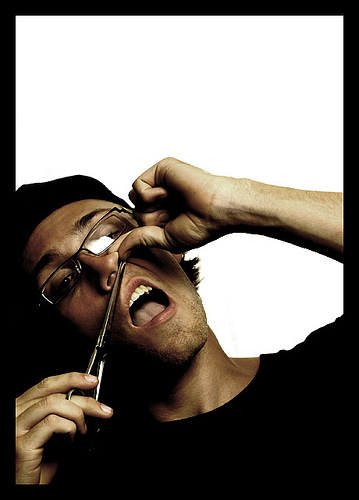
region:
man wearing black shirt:
[267, 401, 341, 461]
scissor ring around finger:
[61, 388, 78, 400]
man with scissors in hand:
[62, 352, 118, 432]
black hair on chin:
[171, 330, 200, 354]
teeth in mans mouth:
[134, 286, 146, 295]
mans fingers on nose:
[110, 240, 131, 257]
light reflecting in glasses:
[87, 238, 112, 249]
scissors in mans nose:
[115, 257, 126, 267]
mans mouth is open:
[119, 278, 179, 327]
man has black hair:
[187, 257, 198, 279]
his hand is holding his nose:
[108, 157, 225, 263]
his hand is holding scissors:
[13, 260, 123, 480]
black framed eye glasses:
[37, 212, 129, 307]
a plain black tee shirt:
[54, 316, 357, 487]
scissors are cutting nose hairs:
[68, 240, 128, 407]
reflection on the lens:
[86, 234, 113, 254]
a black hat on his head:
[15, 173, 135, 251]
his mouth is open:
[125, 278, 175, 331]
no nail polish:
[98, 402, 111, 413]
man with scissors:
[24, 166, 356, 479]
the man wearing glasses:
[33, 200, 139, 323]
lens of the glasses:
[47, 262, 72, 294]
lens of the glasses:
[88, 217, 120, 258]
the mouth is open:
[116, 280, 180, 336]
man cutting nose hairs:
[20, 152, 338, 496]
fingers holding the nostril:
[108, 227, 170, 253]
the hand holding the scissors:
[9, 256, 136, 477]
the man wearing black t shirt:
[41, 312, 357, 480]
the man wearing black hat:
[3, 166, 112, 260]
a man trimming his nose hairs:
[14, 155, 342, 485]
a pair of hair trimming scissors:
[67, 260, 126, 436]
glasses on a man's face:
[36, 202, 137, 311]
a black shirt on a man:
[44, 313, 341, 483]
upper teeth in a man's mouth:
[126, 281, 152, 308]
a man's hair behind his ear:
[178, 254, 202, 292]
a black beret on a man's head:
[15, 174, 130, 256]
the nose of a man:
[75, 248, 120, 293]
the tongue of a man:
[132, 300, 164, 327]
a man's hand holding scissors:
[15, 371, 113, 484]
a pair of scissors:
[65, 247, 132, 410]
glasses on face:
[31, 202, 142, 314]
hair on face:
[134, 264, 211, 374]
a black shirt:
[38, 316, 341, 498]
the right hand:
[16, 365, 114, 486]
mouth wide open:
[120, 267, 177, 334]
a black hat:
[13, 173, 133, 254]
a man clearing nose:
[113, 255, 129, 271]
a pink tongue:
[134, 301, 166, 324]